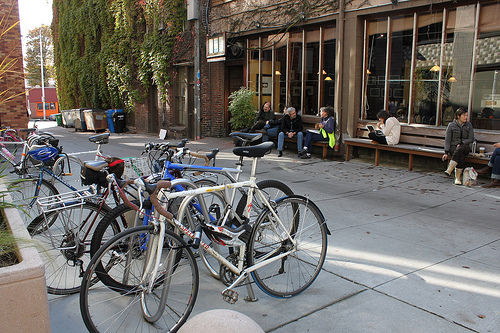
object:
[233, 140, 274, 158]
seat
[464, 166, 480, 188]
bag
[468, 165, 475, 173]
handles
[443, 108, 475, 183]
person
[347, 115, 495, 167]
bench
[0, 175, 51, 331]
concrete planter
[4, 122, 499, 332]
sidewalk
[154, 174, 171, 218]
handle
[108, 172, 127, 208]
handle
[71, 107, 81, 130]
cans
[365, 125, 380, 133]
laptop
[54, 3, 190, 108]
ivy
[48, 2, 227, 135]
wall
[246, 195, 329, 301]
wheel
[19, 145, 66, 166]
helmet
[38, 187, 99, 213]
rack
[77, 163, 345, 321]
bike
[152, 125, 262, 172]
bike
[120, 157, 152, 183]
basket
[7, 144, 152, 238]
bicycle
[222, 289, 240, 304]
bike pedal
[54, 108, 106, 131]
row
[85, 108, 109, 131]
cans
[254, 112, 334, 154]
bench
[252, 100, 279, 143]
people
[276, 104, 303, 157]
people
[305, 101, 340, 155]
people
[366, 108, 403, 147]
people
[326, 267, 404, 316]
crack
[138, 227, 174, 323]
bike rack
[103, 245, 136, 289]
spokes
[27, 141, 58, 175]
handle bars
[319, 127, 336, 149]
sweater